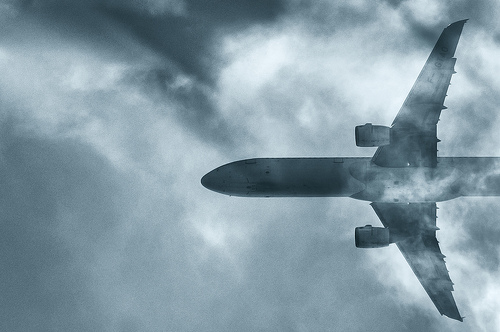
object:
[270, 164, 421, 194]
underbelly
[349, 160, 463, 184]
jet engine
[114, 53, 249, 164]
clouds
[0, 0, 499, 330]
sky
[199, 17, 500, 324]
plane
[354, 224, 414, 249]
engines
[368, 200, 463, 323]
wings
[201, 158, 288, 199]
nose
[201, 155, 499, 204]
body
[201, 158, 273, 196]
cockpit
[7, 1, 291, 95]
cloud